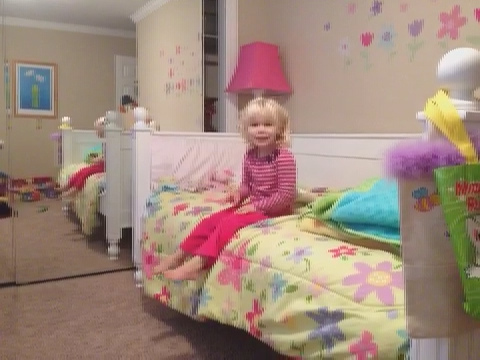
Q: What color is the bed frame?
A: White.